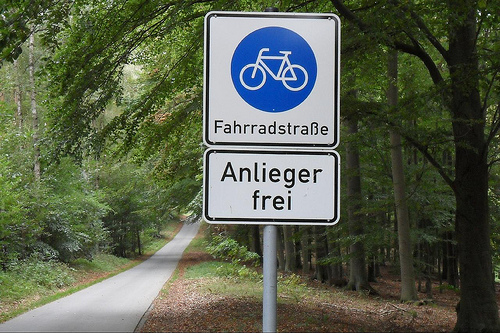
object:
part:
[210, 23, 234, 47]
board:
[201, 11, 341, 151]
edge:
[208, 5, 254, 11]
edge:
[179, 261, 189, 276]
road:
[0, 220, 201, 333]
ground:
[159, 291, 228, 324]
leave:
[206, 294, 226, 304]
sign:
[201, 11, 342, 226]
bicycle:
[239, 47, 309, 92]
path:
[213, 141, 336, 155]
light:
[182, 213, 190, 215]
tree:
[342, 0, 500, 333]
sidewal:
[157, 290, 215, 331]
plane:
[1, 193, 83, 259]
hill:
[30, 165, 112, 271]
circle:
[230, 26, 318, 113]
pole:
[263, 225, 278, 331]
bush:
[8, 249, 70, 285]